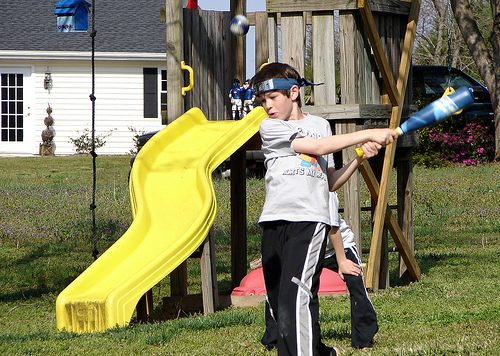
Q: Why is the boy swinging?
A: To hit a ball.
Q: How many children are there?
A: Two.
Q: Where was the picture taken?
A: The backyard.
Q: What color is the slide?
A: Yellow.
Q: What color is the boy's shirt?
A: White.